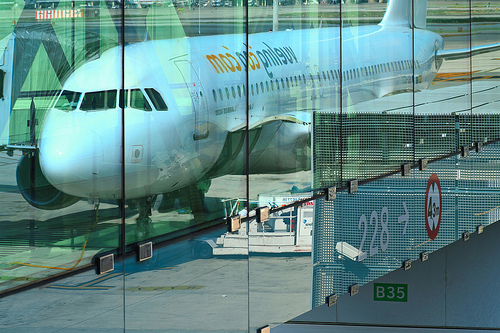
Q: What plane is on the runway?
A: White.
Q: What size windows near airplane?
A: Large.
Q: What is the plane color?
A: It's white.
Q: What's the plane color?
A: It's white.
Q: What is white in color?
A: The plane.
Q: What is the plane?
A: White.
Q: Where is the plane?
A: On the ground.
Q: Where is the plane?
A: Airport.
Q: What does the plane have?
A: Windows.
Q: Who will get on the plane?
A: Passengers.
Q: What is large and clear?
A: Windshield.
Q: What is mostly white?
A: Plane.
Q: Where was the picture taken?
A: Airport.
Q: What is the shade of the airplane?
A: White.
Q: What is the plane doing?
A: Parked.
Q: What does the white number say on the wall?
A: 228.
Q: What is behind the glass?
A: Airplane.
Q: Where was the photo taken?
A: Airport.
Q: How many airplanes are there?
A: 1.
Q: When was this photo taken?
A: During the day.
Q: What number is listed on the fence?
A: 228.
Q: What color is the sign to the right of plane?
A: White & red.